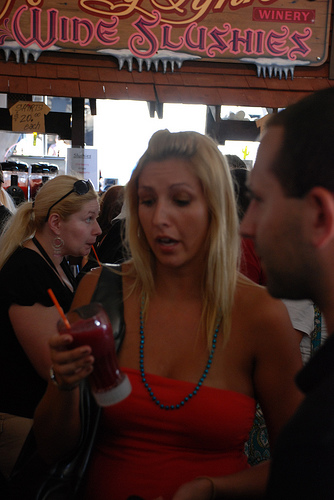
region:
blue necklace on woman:
[128, 289, 238, 420]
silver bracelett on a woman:
[42, 362, 59, 413]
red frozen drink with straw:
[43, 299, 126, 423]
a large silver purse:
[14, 251, 139, 495]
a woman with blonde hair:
[57, 131, 249, 486]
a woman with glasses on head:
[8, 169, 103, 254]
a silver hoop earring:
[35, 224, 76, 264]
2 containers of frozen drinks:
[0, 142, 62, 202]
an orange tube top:
[71, 377, 255, 498]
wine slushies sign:
[1, 10, 307, 64]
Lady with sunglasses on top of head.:
[61, 172, 108, 253]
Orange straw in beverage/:
[39, 288, 96, 338]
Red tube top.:
[92, 354, 247, 499]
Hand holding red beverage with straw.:
[46, 284, 132, 408]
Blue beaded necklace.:
[127, 260, 221, 415]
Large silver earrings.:
[43, 235, 77, 271]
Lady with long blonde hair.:
[108, 125, 240, 332]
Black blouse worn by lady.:
[8, 185, 79, 404]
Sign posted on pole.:
[55, 141, 107, 184]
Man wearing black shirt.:
[246, 137, 328, 491]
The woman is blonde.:
[117, 117, 243, 347]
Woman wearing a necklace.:
[121, 256, 236, 412]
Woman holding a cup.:
[43, 284, 136, 408]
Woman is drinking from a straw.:
[31, 173, 108, 277]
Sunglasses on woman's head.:
[42, 174, 95, 226]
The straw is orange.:
[43, 285, 76, 328]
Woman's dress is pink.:
[93, 355, 260, 496]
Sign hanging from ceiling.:
[1, 1, 328, 71]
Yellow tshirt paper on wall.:
[6, 93, 50, 136]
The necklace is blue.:
[129, 276, 225, 413]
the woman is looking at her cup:
[35, 139, 272, 449]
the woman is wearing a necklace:
[94, 123, 241, 453]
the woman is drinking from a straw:
[29, 161, 107, 260]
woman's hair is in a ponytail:
[1, 190, 55, 252]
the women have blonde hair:
[15, 131, 251, 344]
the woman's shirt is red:
[95, 359, 254, 499]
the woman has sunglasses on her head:
[36, 171, 104, 228]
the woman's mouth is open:
[143, 221, 196, 269]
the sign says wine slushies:
[3, 0, 332, 76]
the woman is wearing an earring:
[129, 218, 148, 249]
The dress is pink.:
[85, 356, 261, 489]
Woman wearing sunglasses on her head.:
[37, 175, 91, 234]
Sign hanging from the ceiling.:
[3, 1, 327, 72]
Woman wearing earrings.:
[46, 229, 67, 261]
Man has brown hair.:
[249, 83, 332, 208]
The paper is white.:
[61, 142, 102, 196]